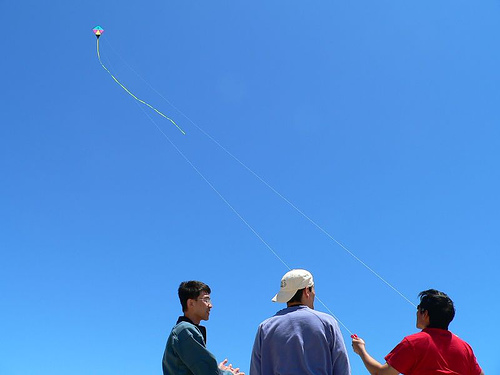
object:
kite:
[92, 25, 188, 143]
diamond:
[93, 26, 102, 39]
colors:
[94, 23, 103, 39]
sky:
[1, 0, 500, 375]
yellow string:
[94, 38, 185, 135]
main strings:
[97, 50, 354, 337]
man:
[350, 288, 487, 375]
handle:
[347, 329, 358, 346]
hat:
[267, 267, 316, 305]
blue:
[246, 303, 350, 374]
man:
[250, 267, 352, 374]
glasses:
[192, 293, 210, 305]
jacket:
[162, 313, 239, 375]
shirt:
[248, 307, 353, 373]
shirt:
[383, 327, 484, 374]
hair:
[178, 281, 213, 311]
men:
[160, 277, 245, 375]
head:
[176, 278, 214, 325]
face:
[193, 288, 212, 322]